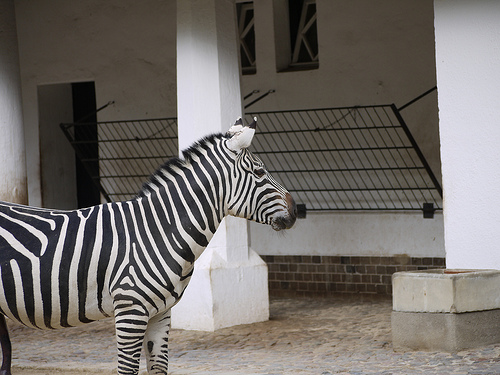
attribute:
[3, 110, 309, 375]
zebra — standing, black, white, vertical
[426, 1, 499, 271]
post — white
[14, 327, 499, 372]
ground — white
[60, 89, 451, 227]
grills — metallic, black, metal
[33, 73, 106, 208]
doorway — open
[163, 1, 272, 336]
pillar — white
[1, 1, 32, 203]
post — white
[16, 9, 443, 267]
wall — white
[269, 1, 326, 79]
window — open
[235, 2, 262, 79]
window — open